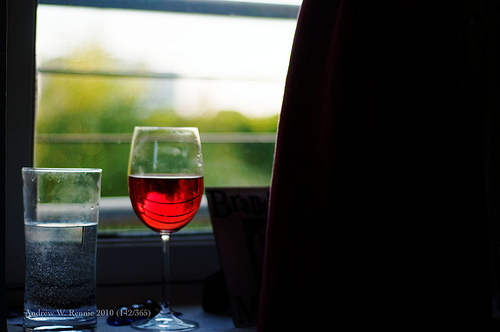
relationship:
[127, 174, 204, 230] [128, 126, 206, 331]
wine in glass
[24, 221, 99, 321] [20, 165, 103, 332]
water in glass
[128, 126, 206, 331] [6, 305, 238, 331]
glass on table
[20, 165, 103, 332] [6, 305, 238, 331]
glass on table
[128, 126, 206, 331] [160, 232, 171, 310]
glass has stem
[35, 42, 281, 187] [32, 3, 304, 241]
trees outside window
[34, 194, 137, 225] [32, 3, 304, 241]
bar in window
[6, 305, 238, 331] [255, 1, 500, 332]
table next to chair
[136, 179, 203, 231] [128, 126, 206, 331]
reflection in glass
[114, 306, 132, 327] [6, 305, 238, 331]
bead on table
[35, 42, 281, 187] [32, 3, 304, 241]
trees outside of window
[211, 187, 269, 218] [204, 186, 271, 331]
letters on frame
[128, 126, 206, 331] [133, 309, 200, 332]
glass has base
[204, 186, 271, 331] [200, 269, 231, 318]
frame has support